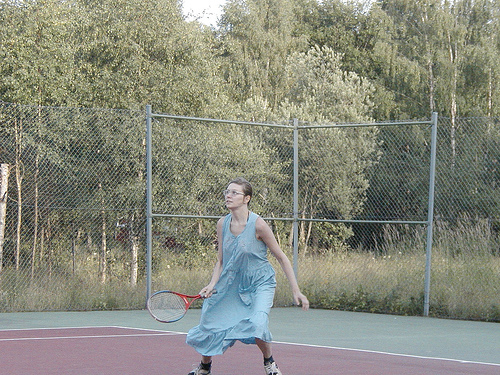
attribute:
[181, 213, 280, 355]
dress — blue, long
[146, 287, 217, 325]
racket — multicolored, red, black, blue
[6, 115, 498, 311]
fence — tall, chain linked, metal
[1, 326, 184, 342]
lines — white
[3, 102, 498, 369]
tennis court — here